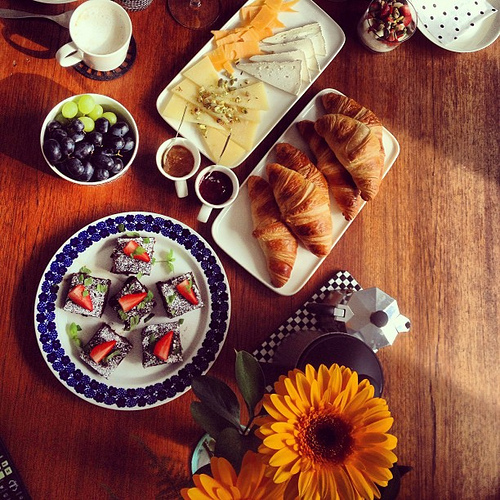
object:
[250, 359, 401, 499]
flower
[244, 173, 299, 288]
bread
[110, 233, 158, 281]
brownie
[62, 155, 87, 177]
grapes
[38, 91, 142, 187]
bowl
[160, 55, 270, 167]
cheese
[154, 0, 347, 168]
plate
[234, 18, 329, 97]
cheese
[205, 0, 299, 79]
cheese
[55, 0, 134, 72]
mug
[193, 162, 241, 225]
cup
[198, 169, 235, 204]
jam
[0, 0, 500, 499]
table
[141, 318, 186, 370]
brownie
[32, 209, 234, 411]
plate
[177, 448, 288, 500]
flower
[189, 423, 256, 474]
vase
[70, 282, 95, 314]
strawberry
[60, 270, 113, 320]
brownie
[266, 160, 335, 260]
bread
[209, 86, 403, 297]
plate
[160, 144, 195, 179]
jam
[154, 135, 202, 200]
cup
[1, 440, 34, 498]
remote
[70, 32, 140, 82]
coaster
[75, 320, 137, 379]
brownie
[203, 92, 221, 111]
nuts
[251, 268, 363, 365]
napkin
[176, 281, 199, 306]
strawberry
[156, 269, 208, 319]
brownie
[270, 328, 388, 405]
kettle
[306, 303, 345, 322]
handle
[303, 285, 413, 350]
bottle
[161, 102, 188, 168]
toothepick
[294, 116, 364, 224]
bread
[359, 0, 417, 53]
parfait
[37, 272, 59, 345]
trim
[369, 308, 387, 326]
knob